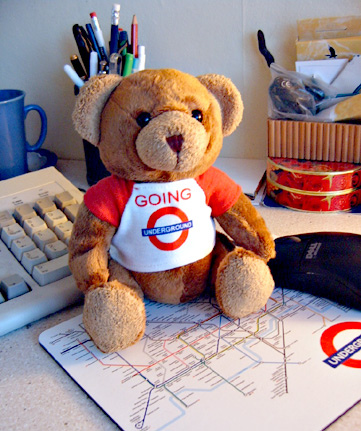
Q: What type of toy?
A: Teddy bear.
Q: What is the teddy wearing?
A: A shirt.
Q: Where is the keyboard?
A: Next to the bear.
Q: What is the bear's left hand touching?
A: Computer mouse.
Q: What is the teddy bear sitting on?
A: Mouse pad.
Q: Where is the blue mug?
A: Behind the keyboard.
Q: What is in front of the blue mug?
A: Keyboard.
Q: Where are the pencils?
A: Behind the bear.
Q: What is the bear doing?
A: Sitting.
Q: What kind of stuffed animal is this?
A: Bear.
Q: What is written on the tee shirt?
A: Going underground.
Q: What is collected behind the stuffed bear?
A: Pens and pencils.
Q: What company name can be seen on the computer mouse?
A: Dell.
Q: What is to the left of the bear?
A: Keyboard.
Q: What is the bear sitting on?
A: Map.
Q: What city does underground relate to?
A: London.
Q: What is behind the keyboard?
A: Blue mug.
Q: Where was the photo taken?
A: In an office.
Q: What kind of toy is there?
A: A teddy bear.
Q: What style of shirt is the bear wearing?
A: A t-shirt.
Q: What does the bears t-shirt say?
A: GOING UNDERGROUND.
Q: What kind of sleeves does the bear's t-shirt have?
A: Short sleeves.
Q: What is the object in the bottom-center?
A: A mousepad.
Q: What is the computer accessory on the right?
A: A mouse.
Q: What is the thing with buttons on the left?
A: A keyboard.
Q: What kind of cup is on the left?
A: A mug.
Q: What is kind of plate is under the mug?
A: A saucer.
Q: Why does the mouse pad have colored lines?
A: It depicts a map of the London transit system.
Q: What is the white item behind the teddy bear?
A: Keyboard.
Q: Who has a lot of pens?
A: The owner of the blue cup directly behind the bear.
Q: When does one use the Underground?
A: When one has to go somewhere in the city.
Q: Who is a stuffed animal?
A: The teddy bear.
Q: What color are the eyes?
A: Black.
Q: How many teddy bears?
A: One.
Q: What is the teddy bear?
A: A stuffed animal.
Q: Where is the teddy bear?
A: On the desk.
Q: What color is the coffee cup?
A: Blue.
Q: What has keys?
A: The keyboard.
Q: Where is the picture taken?
A: If the home office.